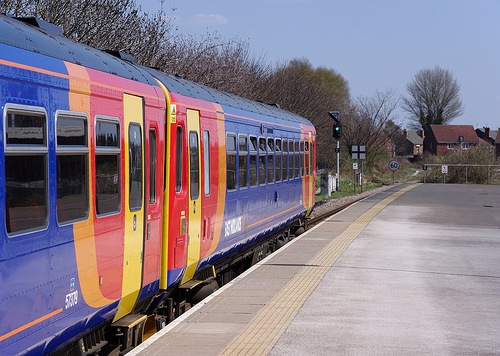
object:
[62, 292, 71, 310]
number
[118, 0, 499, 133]
blue sky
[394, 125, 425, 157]
house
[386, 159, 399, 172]
sign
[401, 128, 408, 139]
chimney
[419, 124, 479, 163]
house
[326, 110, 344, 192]
light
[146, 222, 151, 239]
handle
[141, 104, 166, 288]
door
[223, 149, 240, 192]
window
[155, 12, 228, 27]
cloud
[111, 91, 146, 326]
door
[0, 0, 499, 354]
background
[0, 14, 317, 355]
railroad cart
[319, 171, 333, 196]
power box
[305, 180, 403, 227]
railroad track